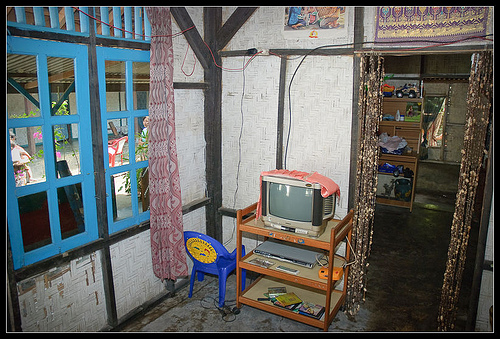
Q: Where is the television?
A: On the wooden stand.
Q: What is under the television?
A: A wooden stand.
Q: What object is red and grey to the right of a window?
A: Curtains.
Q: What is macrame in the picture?
A: The curtain.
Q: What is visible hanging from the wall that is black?
A: Wires.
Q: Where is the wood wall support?
A: Corner.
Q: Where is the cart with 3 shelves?
A: Under the television.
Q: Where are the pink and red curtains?
A: To the left of the television.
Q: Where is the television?
A: On a orange stand.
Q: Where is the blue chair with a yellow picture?
A: To the left of a cart.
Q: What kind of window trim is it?
A: Blue.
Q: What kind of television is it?
A: Black and white.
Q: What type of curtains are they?
A: Red and white.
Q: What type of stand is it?
A: Wooden.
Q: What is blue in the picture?
A: Window frame.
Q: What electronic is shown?
A: The TV.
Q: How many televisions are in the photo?
A: One.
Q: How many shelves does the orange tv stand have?
A: Three.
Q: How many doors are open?
A: One.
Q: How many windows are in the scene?
A: One.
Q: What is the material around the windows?
A: Curtains.